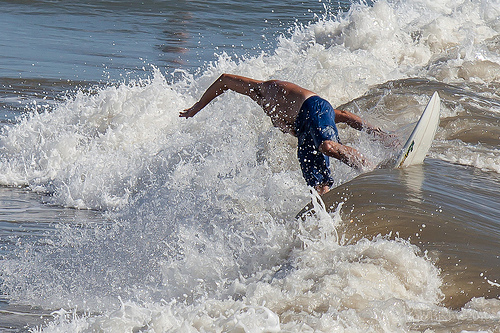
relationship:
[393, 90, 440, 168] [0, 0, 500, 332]
board in water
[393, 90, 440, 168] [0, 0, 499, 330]
board in wave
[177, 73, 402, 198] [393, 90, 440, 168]
man riding board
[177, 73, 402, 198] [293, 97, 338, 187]
man wearing trunk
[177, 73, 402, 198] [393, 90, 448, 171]
man falling off of surfboard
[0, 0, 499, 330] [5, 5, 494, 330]
wave in ocean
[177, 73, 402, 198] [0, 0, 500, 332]
man in water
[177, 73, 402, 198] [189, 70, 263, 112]
man has arm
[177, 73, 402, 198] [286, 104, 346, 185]
man wearing shorts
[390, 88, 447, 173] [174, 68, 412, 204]
board under man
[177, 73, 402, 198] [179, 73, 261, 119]
man has arm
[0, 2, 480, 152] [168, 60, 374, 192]
water under man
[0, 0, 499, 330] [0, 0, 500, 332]
wave in water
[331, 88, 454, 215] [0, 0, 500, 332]
reflection in water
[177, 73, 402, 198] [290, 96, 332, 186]
man wearing shorts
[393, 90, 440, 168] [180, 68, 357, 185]
board ridden by surfer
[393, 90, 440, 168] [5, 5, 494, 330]
board in ocean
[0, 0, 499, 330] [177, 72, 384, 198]
wave ridden by surfer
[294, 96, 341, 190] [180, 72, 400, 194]
shorts worn by surfer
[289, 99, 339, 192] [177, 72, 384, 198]
shorts worn by surfer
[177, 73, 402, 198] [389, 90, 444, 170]
man on surf board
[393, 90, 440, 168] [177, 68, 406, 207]
board of surfer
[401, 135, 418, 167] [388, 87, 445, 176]
lettering on surfboard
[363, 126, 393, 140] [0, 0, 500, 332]
hand in water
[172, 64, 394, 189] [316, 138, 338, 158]
man has knee